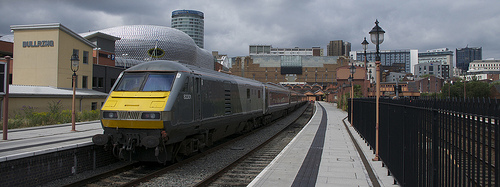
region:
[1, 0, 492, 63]
Gray clouds in the sky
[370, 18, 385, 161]
A lantern on a pole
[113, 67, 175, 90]
Windshield on a train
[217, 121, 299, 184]
Railroad tracks on the ground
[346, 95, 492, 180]
A black painted fence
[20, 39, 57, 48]
Letters on the side of a building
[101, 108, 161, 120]
Headlights on a train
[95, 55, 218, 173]
Front end of a train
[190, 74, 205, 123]
Door on the side of a train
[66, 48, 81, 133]
Lantern on a pole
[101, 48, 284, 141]
yellow and gray train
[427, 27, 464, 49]
white clouds in blue sky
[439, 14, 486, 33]
white clouds in blue sky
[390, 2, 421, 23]
white clouds in blue sky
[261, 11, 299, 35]
white clouds in blue sky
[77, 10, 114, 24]
white clouds in blue sky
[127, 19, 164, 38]
white clouds in blue sky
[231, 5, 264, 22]
white clouds in blue sky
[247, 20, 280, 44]
white clouds in blue sky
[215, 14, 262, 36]
white clouds in blue sky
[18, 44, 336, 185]
The train is on the train tracks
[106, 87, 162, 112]
The front of the train is yellow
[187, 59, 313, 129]
The side of the train is gray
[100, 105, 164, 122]
The head lights on the train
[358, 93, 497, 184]
The gate is made of metal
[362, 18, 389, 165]
The light pole in the ground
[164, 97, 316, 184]
The gravel on the ground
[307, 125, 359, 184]
The sidewalk is made of concrete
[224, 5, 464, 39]
The sky is very cloudy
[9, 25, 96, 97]
The building is the color beige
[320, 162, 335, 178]
white brick on sidewalk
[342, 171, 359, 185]
white brick on sidewalk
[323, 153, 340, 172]
white brick on sidewalk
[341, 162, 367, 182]
white brick on sidewalk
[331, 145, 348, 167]
white brick on sidewalk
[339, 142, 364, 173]
white brick on sidewalk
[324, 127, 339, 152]
white brick on sidewalk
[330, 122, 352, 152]
white brick on sidewalk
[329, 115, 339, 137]
white brick on sidewalk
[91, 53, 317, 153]
train on the tracks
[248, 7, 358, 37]
dark cloudy sky in the distance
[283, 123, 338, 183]
railroad tracks under the trains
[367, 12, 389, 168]
lamp on a post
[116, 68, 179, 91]
front windows on a train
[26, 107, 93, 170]
platform next to a train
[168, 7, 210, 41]
skyscraper in the distance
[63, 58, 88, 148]
sign on a pole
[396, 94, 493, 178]
fence along side of railroad tracks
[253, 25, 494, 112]
city buildings in the background